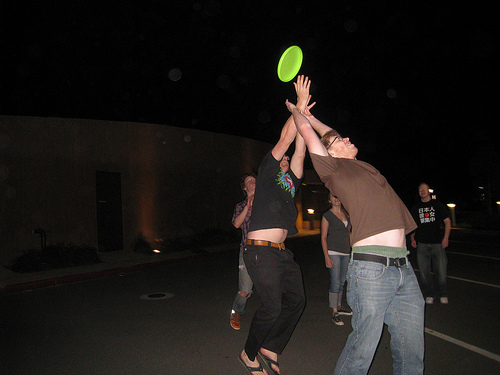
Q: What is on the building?
A: Door.